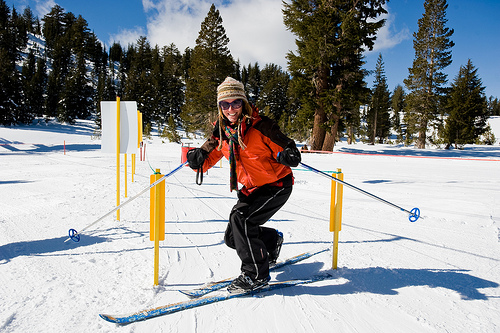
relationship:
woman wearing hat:
[183, 76, 299, 293] [215, 73, 254, 148]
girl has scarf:
[176, 69, 303, 296] [215, 117, 249, 188]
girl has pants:
[176, 69, 303, 296] [217, 170, 294, 283]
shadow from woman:
[281, 233, 495, 308] [183, 76, 299, 293]